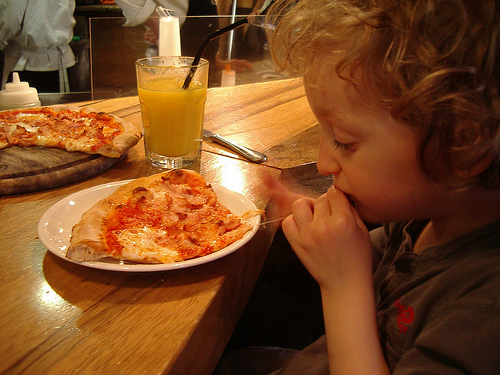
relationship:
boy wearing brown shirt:
[255, 2, 498, 370] [270, 225, 499, 374]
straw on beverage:
[178, 25, 258, 89] [140, 75, 201, 161]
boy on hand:
[255, 0, 500, 375] [275, 185, 378, 285]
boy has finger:
[255, 0, 500, 375] [290, 198, 314, 224]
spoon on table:
[202, 127, 273, 165] [0, 72, 315, 373]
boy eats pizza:
[255, 0, 500, 375] [46, 162, 281, 277]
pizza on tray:
[0, 102, 143, 156] [0, 130, 120, 192]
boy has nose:
[255, 0, 500, 375] [315, 124, 340, 174]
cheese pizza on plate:
[63, 165, 248, 259] [42, 177, 270, 273]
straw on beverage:
[178, 25, 258, 89] [137, 77, 207, 158]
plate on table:
[42, 177, 270, 273] [0, 72, 315, 373]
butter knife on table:
[197, 128, 272, 164] [0, 72, 315, 373]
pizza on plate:
[69, 166, 252, 264] [33, 170, 268, 294]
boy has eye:
[255, 0, 500, 375] [327, 128, 359, 149]